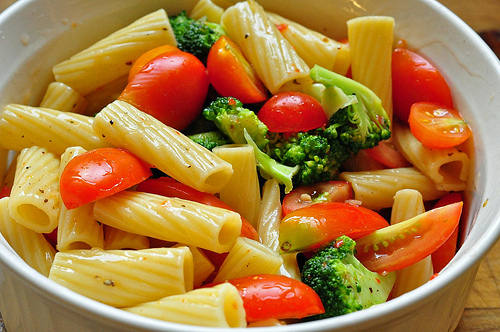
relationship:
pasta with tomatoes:
[13, 15, 308, 328] [48, 30, 316, 206]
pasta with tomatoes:
[2, 1, 469, 328] [51, 33, 323, 218]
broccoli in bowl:
[165, 16, 391, 318] [3, 3, 497, 330]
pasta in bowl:
[2, 1, 469, 328] [3, 3, 497, 330]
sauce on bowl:
[413, 27, 484, 78] [3, 3, 497, 330]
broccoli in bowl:
[169, 14, 221, 63] [3, 3, 497, 330]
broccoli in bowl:
[190, 64, 396, 186] [3, 3, 497, 330]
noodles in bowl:
[2, 83, 248, 305] [3, 3, 497, 330]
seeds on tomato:
[358, 224, 426, 256] [355, 198, 465, 274]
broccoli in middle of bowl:
[219, 112, 336, 201] [3, 3, 497, 330]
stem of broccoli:
[302, 57, 388, 107] [303, 63, 402, 163]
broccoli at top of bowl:
[169, 14, 221, 63] [3, 3, 497, 330]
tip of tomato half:
[278, 218, 324, 257] [272, 202, 391, 257]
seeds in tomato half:
[420, 105, 463, 133] [402, 91, 475, 153]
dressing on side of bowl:
[13, 13, 85, 103] [3, 3, 497, 330]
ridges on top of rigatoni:
[114, 114, 173, 152] [85, 96, 237, 197]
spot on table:
[469, 292, 484, 309] [473, 288, 479, 292]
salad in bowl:
[67, 34, 407, 253] [3, 3, 497, 330]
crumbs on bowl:
[15, 20, 71, 40] [3, 3, 497, 330]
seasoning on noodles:
[83, 269, 122, 294] [104, 94, 239, 194]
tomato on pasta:
[58, 142, 159, 203] [2, 1, 469, 328]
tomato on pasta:
[119, 50, 209, 126] [2, 1, 469, 328]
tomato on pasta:
[205, 38, 262, 101] [2, 1, 469, 328]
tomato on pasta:
[260, 91, 326, 134] [2, 1, 469, 328]